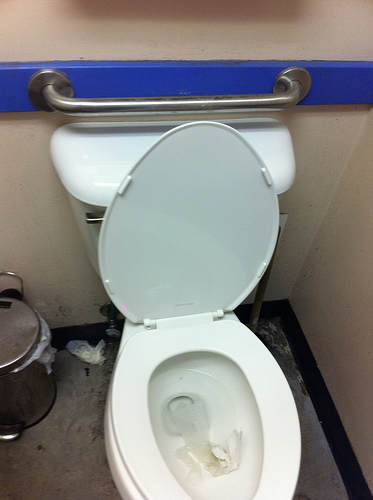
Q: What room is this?
A: It is a bathroom.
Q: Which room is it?
A: It is a bathroom.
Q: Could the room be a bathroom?
A: Yes, it is a bathroom.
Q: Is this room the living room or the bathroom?
A: It is the bathroom.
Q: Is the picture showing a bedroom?
A: No, the picture is showing a bathroom.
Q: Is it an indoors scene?
A: Yes, it is indoors.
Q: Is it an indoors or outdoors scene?
A: It is indoors.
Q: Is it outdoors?
A: No, it is indoors.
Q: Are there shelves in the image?
A: No, there are no shelves.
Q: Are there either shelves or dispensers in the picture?
A: No, there are no shelves or dispensers.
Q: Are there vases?
A: No, there are no vases.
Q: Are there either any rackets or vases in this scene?
A: No, there are no vases or rackets.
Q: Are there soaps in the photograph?
A: No, there are no soaps.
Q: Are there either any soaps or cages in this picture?
A: No, there are no soaps or cages.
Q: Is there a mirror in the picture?
A: No, there are no mirrors.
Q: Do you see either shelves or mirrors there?
A: No, there are no mirrors or shelves.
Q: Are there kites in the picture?
A: No, there are no kites.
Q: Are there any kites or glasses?
A: No, there are no kites or glasses.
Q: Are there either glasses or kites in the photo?
A: No, there are no kites or glasses.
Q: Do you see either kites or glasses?
A: No, there are no kites or glasses.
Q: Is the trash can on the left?
A: Yes, the trash can is on the left of the image.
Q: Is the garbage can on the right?
A: No, the garbage can is on the left of the image.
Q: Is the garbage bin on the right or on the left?
A: The garbage bin is on the left of the image.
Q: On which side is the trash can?
A: The trash can is on the left of the image.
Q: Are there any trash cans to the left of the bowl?
A: Yes, there is a trash can to the left of the bowl.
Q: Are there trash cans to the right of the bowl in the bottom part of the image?
A: No, the trash can is to the left of the bowl.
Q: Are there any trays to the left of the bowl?
A: No, there is a trash can to the left of the bowl.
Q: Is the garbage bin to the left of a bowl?
A: Yes, the garbage bin is to the left of a bowl.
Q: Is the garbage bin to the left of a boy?
A: No, the garbage bin is to the left of a bowl.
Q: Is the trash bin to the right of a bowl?
A: No, the trash bin is to the left of a bowl.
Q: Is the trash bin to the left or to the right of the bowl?
A: The trash bin is to the left of the bowl.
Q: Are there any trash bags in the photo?
A: Yes, there is a trash bag.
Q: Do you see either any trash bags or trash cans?
A: Yes, there is a trash bag.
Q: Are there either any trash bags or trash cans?
A: Yes, there is a trash bag.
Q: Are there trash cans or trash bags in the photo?
A: Yes, there is a trash bag.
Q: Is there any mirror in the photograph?
A: No, there are no mirrors.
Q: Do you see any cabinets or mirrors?
A: No, there are no mirrors or cabinets.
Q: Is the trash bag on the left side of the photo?
A: Yes, the trash bag is on the left of the image.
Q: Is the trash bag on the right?
A: No, the trash bag is on the left of the image.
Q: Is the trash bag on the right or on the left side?
A: The trash bag is on the left of the image.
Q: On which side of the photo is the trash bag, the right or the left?
A: The trash bag is on the left of the image.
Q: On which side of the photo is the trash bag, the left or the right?
A: The trash bag is on the left of the image.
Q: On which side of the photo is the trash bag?
A: The trash bag is on the left of the image.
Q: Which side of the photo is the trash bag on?
A: The trash bag is on the left of the image.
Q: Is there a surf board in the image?
A: No, there are no surfboards.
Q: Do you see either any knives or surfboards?
A: No, there are no surfboards or knives.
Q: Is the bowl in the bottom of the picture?
A: Yes, the bowl is in the bottom of the image.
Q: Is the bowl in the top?
A: No, the bowl is in the bottom of the image.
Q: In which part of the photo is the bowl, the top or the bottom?
A: The bowl is in the bottom of the image.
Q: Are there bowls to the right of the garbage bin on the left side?
A: Yes, there is a bowl to the right of the trash bin.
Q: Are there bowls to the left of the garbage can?
A: No, the bowl is to the right of the garbage can.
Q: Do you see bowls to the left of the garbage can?
A: No, the bowl is to the right of the garbage can.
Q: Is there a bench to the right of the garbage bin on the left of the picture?
A: No, there is a bowl to the right of the trash can.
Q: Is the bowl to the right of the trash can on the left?
A: Yes, the bowl is to the right of the trash can.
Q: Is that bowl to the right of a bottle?
A: No, the bowl is to the right of the trash can.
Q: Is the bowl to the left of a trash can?
A: No, the bowl is to the right of a trash can.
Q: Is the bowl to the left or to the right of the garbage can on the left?
A: The bowl is to the right of the trash can.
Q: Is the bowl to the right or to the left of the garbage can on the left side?
A: The bowl is to the right of the trash can.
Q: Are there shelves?
A: No, there are no shelves.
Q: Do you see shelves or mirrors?
A: No, there are no shelves or mirrors.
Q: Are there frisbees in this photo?
A: No, there are no frisbees.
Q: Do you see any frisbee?
A: No, there are no frisbees.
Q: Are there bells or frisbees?
A: No, there are no frisbees or bells.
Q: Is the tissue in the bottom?
A: Yes, the tissue is in the bottom of the image.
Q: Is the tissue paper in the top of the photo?
A: No, the tissue paper is in the bottom of the image.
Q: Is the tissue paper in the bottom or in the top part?
A: The tissue paper is in the bottom of the image.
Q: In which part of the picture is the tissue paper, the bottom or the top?
A: The tissue paper is in the bottom of the image.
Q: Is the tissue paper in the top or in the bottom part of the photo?
A: The tissue paper is in the bottom of the image.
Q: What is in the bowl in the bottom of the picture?
A: The tissue is in the bowl.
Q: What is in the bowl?
A: The tissue is in the bowl.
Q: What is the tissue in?
A: The tissue is in the bowl.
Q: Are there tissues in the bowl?
A: Yes, there is a tissue in the bowl.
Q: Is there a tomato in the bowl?
A: No, there is a tissue in the bowl.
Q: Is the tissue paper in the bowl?
A: Yes, the tissue paper is in the bowl.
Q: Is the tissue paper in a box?
A: No, the tissue paper is in the bowl.